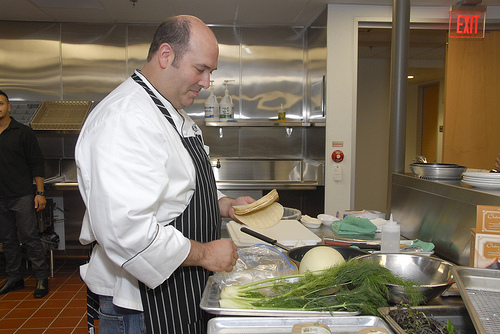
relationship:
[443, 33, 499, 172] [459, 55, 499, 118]
door has a wood color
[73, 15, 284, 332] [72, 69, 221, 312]
man has a shirt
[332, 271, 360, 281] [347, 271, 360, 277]
green looks to be green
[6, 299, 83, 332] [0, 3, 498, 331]
red tile in kitchen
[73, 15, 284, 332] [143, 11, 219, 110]
man has a head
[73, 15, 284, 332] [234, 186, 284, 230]
man holding tortillas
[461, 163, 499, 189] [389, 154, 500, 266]
plates are on line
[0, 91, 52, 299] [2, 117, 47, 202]
man wearing shirt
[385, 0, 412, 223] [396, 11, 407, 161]
pole that visible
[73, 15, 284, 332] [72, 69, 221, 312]
man wearing shirt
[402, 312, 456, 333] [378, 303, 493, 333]
vegetables in a pan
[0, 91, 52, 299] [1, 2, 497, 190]
man standing in background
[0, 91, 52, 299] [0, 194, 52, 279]
man wearing pants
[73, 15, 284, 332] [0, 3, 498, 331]
man working in kitchen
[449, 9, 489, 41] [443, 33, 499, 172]
sign over door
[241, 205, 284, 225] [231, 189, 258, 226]
bread in hand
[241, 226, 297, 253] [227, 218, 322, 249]
knife on board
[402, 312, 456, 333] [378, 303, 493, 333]
vegetables in pan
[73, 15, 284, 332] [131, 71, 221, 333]
man wearing apron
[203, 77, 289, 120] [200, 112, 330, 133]
chemicals on counter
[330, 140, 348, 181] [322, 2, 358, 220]
alarm on wall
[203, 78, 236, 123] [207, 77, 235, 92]
bottles with pump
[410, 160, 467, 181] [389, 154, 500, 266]
plates on shelf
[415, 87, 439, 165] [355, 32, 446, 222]
door dow hall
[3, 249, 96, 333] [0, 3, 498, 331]
floor in kitchen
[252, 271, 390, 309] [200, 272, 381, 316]
herbs in tray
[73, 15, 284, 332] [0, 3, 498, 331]
man in kitchen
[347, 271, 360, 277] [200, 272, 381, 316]
green on tray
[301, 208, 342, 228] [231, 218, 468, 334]
dishes on counter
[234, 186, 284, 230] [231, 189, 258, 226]
shells in left hand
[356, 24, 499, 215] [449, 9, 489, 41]
doorwa with sign